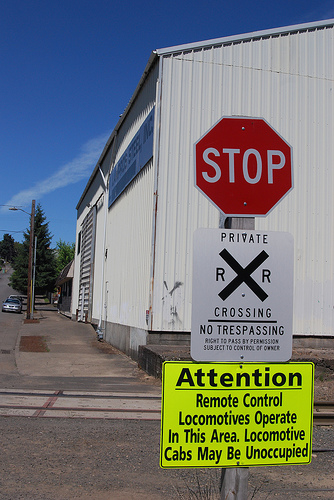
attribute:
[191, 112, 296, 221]
sign — red, octagonal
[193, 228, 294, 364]
sign — warning, for no tresspassing, black, white, railroad crossing, in middle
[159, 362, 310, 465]
sign — warning, yellow-green, yellow, at bottom, neon green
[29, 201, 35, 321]
pole — tall, woode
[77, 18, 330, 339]
building — large, white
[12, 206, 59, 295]
tree — tall, evergreen, pine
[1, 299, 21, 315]
car — parked, silver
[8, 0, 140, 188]
sky — blue, cloudless, clear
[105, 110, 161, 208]
sign — blue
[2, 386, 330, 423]
track — for trains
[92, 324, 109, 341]
meter — for gas, attached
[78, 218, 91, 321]
door — shuttered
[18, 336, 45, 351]
section — brick